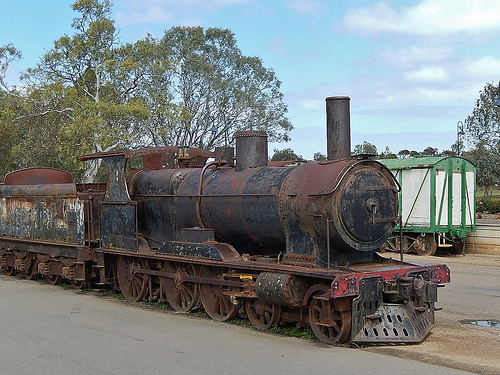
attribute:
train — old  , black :
[64, 126, 417, 339]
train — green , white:
[394, 150, 464, 252]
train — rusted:
[7, 79, 470, 375]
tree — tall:
[68, 65, 135, 131]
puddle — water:
[456, 310, 498, 331]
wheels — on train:
[164, 264, 344, 350]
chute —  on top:
[226, 112, 282, 182]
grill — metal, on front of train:
[311, 279, 475, 353]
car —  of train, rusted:
[5, 160, 93, 285]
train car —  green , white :
[398, 153, 488, 240]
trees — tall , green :
[55, 83, 163, 127]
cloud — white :
[421, 99, 451, 102]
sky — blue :
[418, 107, 454, 137]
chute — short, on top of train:
[230, 129, 274, 170]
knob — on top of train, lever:
[356, 194, 386, 231]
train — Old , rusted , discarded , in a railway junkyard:
[0, 112, 460, 365]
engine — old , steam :
[105, 148, 465, 352]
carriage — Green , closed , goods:
[390, 145, 480, 247]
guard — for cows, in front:
[332, 292, 460, 347]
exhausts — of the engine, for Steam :
[230, 111, 365, 151]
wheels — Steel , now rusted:
[118, 256, 369, 362]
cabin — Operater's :
[91, 147, 151, 260]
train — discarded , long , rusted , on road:
[13, 110, 456, 344]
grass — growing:
[76, 297, 377, 353]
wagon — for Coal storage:
[0, 169, 107, 283]